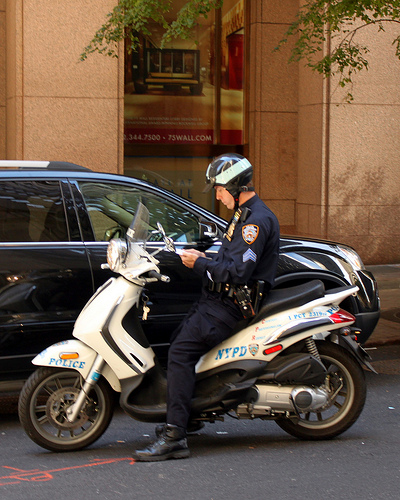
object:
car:
[0, 161, 377, 411]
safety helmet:
[197, 156, 257, 201]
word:
[46, 355, 86, 371]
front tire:
[16, 360, 113, 452]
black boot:
[129, 418, 190, 465]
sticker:
[204, 339, 280, 365]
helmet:
[198, 152, 259, 213]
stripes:
[237, 239, 263, 271]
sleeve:
[184, 209, 284, 287]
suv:
[0, 157, 382, 407]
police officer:
[130, 151, 280, 463]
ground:
[320, 116, 359, 141]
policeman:
[166, 150, 274, 440]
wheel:
[263, 338, 368, 446]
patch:
[239, 248, 262, 267]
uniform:
[212, 209, 273, 276]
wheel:
[12, 369, 119, 460]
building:
[3, 2, 395, 254]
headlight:
[103, 239, 125, 271]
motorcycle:
[19, 203, 373, 449]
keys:
[138, 293, 152, 324]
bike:
[17, 198, 383, 447]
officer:
[126, 149, 283, 463]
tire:
[266, 335, 368, 443]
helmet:
[202, 153, 262, 190]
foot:
[132, 418, 192, 460]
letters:
[206, 337, 248, 359]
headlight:
[60, 349, 78, 362]